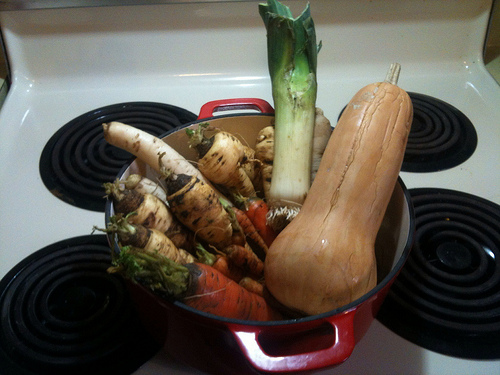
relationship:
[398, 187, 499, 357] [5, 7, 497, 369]
burner on stove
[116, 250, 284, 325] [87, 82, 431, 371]
carrot in pot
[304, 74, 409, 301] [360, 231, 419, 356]
squash in pot